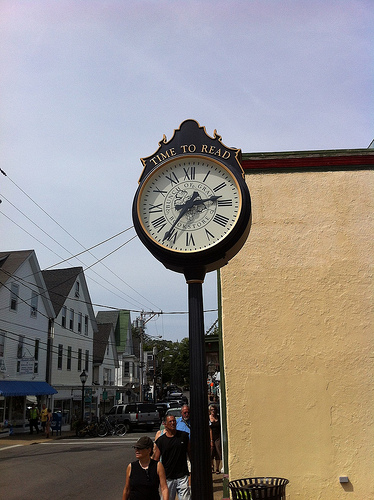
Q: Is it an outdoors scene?
A: Yes, it is outdoors.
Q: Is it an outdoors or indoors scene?
A: It is outdoors.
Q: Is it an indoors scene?
A: No, it is outdoors.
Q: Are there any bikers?
A: No, there are no bikers.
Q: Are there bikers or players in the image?
A: No, there are no bikers or players.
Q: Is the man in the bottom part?
A: Yes, the man is in the bottom of the image.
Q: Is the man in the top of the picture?
A: No, the man is in the bottom of the image.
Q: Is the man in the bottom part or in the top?
A: The man is in the bottom of the image.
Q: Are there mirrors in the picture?
A: No, there are no mirrors.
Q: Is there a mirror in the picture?
A: No, there are no mirrors.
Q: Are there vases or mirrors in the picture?
A: No, there are no mirrors or vases.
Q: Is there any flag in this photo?
A: No, there are no flags.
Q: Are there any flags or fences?
A: No, there are no flags or fences.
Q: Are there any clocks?
A: Yes, there is a clock.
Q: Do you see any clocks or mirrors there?
A: Yes, there is a clock.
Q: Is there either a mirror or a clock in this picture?
A: Yes, there is a clock.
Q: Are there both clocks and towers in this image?
A: No, there is a clock but no towers.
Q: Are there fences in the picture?
A: No, there are no fences.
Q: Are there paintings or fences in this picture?
A: No, there are no fences or paintings.